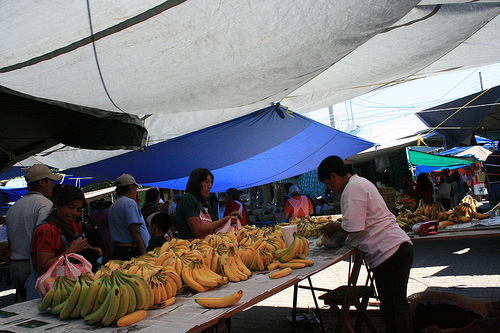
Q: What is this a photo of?
A: Outdoor market.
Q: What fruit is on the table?
A: Bananas.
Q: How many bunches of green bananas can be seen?
A: 4.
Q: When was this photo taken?
A: Daytime.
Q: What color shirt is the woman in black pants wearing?
A: White.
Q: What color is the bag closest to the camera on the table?
A: Pink & white.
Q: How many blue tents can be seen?
A: 1.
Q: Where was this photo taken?
A: At a fruit stand.